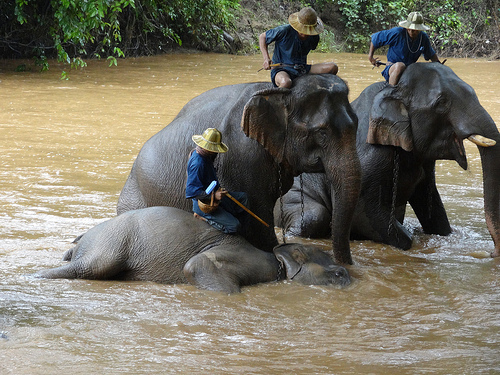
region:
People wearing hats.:
[165, 2, 442, 148]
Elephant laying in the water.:
[81, 215, 377, 302]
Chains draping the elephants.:
[245, 100, 450, 220]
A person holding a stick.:
[198, 179, 287, 239]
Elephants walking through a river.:
[131, 19, 499, 251]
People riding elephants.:
[111, 15, 456, 228]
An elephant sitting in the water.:
[349, 65, 444, 247]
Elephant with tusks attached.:
[433, 113, 498, 170]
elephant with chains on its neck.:
[237, 80, 352, 257]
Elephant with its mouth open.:
[438, 115, 488, 201]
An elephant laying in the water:
[37, 206, 354, 296]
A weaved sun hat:
[190, 128, 228, 155]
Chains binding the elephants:
[276, 158, 287, 250]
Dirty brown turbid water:
[322, 304, 436, 349]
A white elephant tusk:
[467, 133, 494, 148]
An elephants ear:
[241, 88, 290, 163]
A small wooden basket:
[197, 190, 220, 212]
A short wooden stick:
[218, 182, 268, 228]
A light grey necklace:
[405, 22, 423, 52]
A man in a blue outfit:
[185, 126, 254, 236]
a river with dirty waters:
[18, 82, 117, 200]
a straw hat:
[193, 129, 228, 153]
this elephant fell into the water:
[65, 210, 350, 300]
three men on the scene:
[183, 9, 433, 233]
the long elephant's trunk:
[326, 153, 357, 262]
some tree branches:
[22, 2, 227, 62]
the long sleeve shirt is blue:
[186, 159, 220, 198]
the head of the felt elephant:
[278, 246, 348, 288]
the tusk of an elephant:
[469, 133, 495, 148]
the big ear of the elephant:
[246, 85, 291, 160]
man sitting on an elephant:
[167, 117, 266, 247]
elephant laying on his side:
[33, 182, 353, 335]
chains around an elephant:
[259, 158, 319, 244]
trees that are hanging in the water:
[1, 0, 243, 61]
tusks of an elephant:
[461, 133, 495, 152]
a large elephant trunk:
[321, 143, 365, 271]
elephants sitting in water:
[120, 43, 491, 255]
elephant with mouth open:
[441, 119, 475, 168]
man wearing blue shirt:
[185, 157, 248, 228]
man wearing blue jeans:
[191, 192, 250, 235]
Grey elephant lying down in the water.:
[36, 205, 353, 292]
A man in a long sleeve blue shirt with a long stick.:
[188, 126, 250, 234]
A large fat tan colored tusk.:
[465, 130, 497, 149]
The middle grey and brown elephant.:
[116, 73, 363, 260]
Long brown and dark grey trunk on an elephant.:
[319, 153, 361, 269]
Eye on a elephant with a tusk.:
[437, 95, 449, 107]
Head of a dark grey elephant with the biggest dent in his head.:
[280, 71, 360, 172]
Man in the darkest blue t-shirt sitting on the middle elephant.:
[257, 5, 337, 92]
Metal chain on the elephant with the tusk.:
[390, 146, 399, 243]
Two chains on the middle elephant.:
[275, 163, 307, 243]